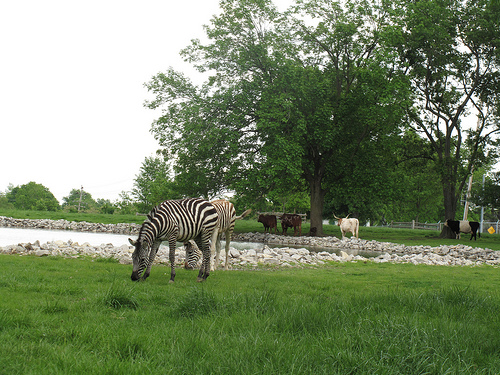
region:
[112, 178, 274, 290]
zebras on the grass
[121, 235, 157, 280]
head of the zebra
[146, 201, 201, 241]
black stripes on the zebra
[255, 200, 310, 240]
animals in the background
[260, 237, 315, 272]
rocks on the ground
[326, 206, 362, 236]
animal in the background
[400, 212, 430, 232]
fence in the distance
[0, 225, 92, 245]
water next to the animals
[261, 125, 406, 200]
trees with many leaves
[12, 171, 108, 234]
trees in the distance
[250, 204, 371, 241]
the cattle by the tree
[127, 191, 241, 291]
zebras eating grass off the ground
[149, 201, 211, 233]
the black and white stripes on the body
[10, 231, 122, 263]
the rock pile near the water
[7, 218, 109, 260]
the water surrounded by rock piles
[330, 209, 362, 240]
the white cattle with brown patched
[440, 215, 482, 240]
a black and white cow in the field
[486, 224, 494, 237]
a yellow sign on the fence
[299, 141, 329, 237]
the trunk of the tree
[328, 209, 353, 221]
the long horns of the cattle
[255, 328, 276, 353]
Small patch of green grass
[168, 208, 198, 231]
Black and white skin of the zebra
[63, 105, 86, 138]
Small patch of the white overcast sky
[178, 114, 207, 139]
Green leaves on the tree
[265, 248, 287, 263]
A group of rocks surrounding the river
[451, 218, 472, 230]
Black and white skin of the cow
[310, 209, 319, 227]
Brown oak of the tree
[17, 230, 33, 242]
Small part of the white water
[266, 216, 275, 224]
Brown skin of the cow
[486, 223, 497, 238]
Yellow sign in the distance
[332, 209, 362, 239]
tan and white cow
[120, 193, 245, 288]
two zebras eating grass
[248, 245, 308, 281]
white rocks near the grass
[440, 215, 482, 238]
black and white cow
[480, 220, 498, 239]
yellow sign on the fence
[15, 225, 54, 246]
pond near the rocks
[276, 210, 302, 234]
brown cow on the grass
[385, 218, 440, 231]
wooden fence behind trees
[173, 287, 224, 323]
tall green grass on the ground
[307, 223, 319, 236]
black spot on the tree trunk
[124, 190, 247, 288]
two zebras grazing on the grass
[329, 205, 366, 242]
brown and tan cow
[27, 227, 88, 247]
pond near the rocks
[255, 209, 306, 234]
two cows near the tree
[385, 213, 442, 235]
wooden fence in the background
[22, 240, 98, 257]
white rocks near the pond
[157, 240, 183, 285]
leg of the zebra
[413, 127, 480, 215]
tree branches on the tree